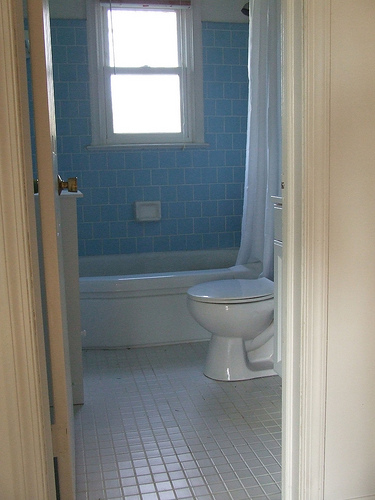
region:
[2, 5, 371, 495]
a toilet in a bathroom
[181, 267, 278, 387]
the toilet is white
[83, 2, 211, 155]
a window in a bathroom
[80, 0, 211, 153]
window has white frame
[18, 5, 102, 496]
a brown door of a bathroom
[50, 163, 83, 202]
knob of door of bathroom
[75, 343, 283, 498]
white tiles on floor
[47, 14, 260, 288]
blue tiles in front bathtub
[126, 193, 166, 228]
a white soap dish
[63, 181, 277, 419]
a white counter in front a toilet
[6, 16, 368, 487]
picture of a bathroom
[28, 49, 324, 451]
picture taken indoors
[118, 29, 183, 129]
picture taken during the day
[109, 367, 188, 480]
white tiles on floor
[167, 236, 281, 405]
a white toilet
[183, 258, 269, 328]
the toilet seat is down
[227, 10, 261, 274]
the shower curtain is open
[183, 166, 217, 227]
the tiles on wall are blue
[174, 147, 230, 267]
the grout is white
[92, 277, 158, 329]
the bathtub is white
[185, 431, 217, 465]
The floor of this bathroom is a very bright white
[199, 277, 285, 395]
This toilet is a very, very bright white color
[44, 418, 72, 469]
This is a very, very white door hinge here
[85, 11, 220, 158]
This is a lovely bathroom window here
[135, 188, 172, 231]
There is a soap container here for the shower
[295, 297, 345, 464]
There is some moulding around the door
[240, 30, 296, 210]
There is a very bright white shower curtain visible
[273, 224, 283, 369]
There is a very bright white vanity visible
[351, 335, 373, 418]
There is a white wall here that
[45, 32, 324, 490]
Jackson Mingus took this photo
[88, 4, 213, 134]
window in the room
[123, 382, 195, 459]
floor next to toilet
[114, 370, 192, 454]
squares on the floor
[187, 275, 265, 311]
lid of the toilet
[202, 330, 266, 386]
bottom of the toilet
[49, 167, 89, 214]
knob on the door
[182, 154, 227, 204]
blue wall with white lines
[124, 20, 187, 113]
light in the window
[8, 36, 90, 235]
open door in photo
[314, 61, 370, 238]
wall outside the bathroom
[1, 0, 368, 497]
A bathroom.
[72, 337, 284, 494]
A white tile floor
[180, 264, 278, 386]
A white toilet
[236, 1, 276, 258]
A white shower curtain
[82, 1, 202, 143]
A white framed window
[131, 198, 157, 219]
A soap holder.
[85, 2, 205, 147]
A window with the blinds pulled up.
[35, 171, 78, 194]
A dark colored door knob.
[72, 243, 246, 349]
A white bathtub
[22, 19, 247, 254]
Blue tiles on the wall.